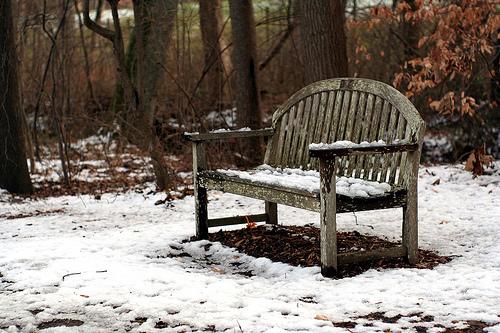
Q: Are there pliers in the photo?
A: No, there are no pliers.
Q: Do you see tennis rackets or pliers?
A: No, there are no pliers or tennis rackets.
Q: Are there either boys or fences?
A: No, there are no fences or boys.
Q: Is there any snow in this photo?
A: Yes, there is snow.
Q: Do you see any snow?
A: Yes, there is snow.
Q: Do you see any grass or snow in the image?
A: Yes, there is snow.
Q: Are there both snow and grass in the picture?
A: No, there is snow but no grass.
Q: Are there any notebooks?
A: No, there are no notebooks.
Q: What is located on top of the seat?
A: The snow is on top of the seat.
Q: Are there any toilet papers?
A: No, there are no toilet papers.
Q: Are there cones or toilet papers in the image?
A: No, there are no toilet papers or cones.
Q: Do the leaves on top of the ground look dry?
A: Yes, the leaves are dry.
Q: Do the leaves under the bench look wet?
A: No, the leaves are dry.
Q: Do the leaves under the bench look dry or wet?
A: The leaves are dry.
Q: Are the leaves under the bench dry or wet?
A: The leaves are dry.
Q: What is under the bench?
A: The leaves are under the bench.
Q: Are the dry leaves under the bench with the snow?
A: Yes, the leaves are under the bench.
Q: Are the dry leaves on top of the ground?
A: Yes, the leaves are on top of the ground.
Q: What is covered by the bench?
A: The leaves are covered by the bench.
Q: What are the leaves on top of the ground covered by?
A: The leaves are covered by the bench.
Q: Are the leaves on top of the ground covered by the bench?
A: Yes, the leaves are covered by the bench.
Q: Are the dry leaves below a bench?
A: Yes, the leaves are below a bench.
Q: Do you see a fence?
A: No, there are no fences.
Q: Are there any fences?
A: No, there are no fences.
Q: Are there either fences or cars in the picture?
A: No, there are no fences or cars.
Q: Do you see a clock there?
A: No, there are no clocks.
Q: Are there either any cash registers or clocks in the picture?
A: No, there are no clocks or cash registers.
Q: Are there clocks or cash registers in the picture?
A: No, there are no clocks or cash registers.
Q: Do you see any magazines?
A: No, there are no magazines.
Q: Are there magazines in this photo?
A: No, there are no magazines.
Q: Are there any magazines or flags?
A: No, there are no magazines or flags.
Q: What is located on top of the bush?
A: The branch is on top of the bush.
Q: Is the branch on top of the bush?
A: Yes, the branch is on top of the bush.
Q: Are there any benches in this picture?
A: Yes, there is a bench.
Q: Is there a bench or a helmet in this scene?
A: Yes, there is a bench.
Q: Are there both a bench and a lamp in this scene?
A: No, there is a bench but no lamps.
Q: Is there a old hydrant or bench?
A: Yes, there is an old bench.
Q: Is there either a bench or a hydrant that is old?
A: Yes, the bench is old.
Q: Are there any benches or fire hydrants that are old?
A: Yes, the bench is old.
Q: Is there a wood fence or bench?
A: Yes, there is a wood bench.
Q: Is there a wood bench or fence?
A: Yes, there is a wood bench.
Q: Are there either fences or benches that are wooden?
A: Yes, the bench is wooden.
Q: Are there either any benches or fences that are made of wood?
A: Yes, the bench is made of wood.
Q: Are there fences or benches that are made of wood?
A: Yes, the bench is made of wood.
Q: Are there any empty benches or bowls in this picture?
A: Yes, there is an empty bench.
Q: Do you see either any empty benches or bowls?
A: Yes, there is an empty bench.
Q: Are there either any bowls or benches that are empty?
A: Yes, the bench is empty.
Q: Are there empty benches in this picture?
A: Yes, there is an empty bench.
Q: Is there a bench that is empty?
A: Yes, there is a bench that is empty.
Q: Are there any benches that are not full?
A: Yes, there is a empty bench.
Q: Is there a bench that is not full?
A: Yes, there is a empty bench.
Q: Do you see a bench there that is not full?
A: Yes, there is a empty bench.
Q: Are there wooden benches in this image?
A: Yes, there is a wood bench.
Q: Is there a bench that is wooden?
A: Yes, there is a bench that is wooden.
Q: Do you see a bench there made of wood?
A: Yes, there is a bench that is made of wood.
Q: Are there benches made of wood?
A: Yes, there is a bench that is made of wood.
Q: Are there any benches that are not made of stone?
A: Yes, there is a bench that is made of wood.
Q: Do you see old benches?
A: Yes, there is an old bench.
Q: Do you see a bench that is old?
A: Yes, there is an old bench.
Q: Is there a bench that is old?
A: Yes, there is a bench that is old.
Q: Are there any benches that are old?
A: Yes, there is a bench that is old.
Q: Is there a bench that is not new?
A: Yes, there is a old bench.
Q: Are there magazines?
A: No, there are no magazines.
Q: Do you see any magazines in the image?
A: No, there are no magazines.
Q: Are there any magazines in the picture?
A: No, there are no magazines.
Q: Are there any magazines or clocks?
A: No, there are no magazines or clocks.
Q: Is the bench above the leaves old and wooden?
A: Yes, the bench is old and wooden.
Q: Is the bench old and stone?
A: No, the bench is old but wooden.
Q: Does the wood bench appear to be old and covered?
A: Yes, the bench is old and covered.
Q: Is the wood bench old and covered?
A: Yes, the bench is old and covered.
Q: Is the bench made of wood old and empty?
A: Yes, the bench is old and empty.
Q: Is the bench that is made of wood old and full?
A: No, the bench is old but empty.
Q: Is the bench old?
A: Yes, the bench is old.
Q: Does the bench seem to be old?
A: Yes, the bench is old.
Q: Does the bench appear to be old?
A: Yes, the bench is old.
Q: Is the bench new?
A: No, the bench is old.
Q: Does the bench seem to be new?
A: No, the bench is old.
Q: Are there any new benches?
A: No, there is a bench but it is old.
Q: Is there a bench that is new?
A: No, there is a bench but it is old.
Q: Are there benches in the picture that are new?
A: No, there is a bench but it is old.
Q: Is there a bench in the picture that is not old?
A: No, there is a bench but it is old.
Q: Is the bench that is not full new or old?
A: The bench is old.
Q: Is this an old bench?
A: Yes, this is an old bench.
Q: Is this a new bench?
A: No, this is an old bench.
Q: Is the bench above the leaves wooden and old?
A: Yes, the bench is wooden and old.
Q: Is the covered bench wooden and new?
A: No, the bench is wooden but old.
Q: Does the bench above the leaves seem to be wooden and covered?
A: Yes, the bench is wooden and covered.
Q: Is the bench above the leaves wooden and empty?
A: Yes, the bench is wooden and empty.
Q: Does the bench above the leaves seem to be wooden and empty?
A: Yes, the bench is wooden and empty.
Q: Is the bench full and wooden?
A: No, the bench is wooden but empty.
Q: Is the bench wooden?
A: Yes, the bench is wooden.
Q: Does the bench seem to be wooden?
A: Yes, the bench is wooden.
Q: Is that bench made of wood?
A: Yes, the bench is made of wood.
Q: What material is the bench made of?
A: The bench is made of wood.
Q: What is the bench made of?
A: The bench is made of wood.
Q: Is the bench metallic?
A: No, the bench is wooden.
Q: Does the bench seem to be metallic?
A: No, the bench is wooden.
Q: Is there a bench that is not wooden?
A: No, there is a bench but it is wooden.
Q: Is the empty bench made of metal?
A: No, the bench is made of wood.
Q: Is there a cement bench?
A: No, there is a bench but it is made of wood.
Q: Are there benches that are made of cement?
A: No, there is a bench but it is made of wood.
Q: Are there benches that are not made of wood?
A: No, there is a bench but it is made of wood.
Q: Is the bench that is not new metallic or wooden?
A: The bench is wooden.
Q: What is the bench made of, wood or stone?
A: The bench is made of wood.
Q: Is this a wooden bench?
A: Yes, this is a wooden bench.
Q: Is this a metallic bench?
A: No, this is a wooden bench.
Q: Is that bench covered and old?
A: Yes, the bench is covered and old.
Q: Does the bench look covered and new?
A: No, the bench is covered but old.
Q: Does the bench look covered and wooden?
A: Yes, the bench is covered and wooden.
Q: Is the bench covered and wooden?
A: Yes, the bench is covered and wooden.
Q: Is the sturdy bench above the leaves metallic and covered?
A: No, the bench is covered but wooden.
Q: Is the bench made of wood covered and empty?
A: Yes, the bench is covered and empty.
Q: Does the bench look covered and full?
A: No, the bench is covered but empty.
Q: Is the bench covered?
A: Yes, the bench is covered.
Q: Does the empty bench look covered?
A: Yes, the bench is covered.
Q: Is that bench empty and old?
A: Yes, the bench is empty and old.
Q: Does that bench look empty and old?
A: Yes, the bench is empty and old.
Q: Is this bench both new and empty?
A: No, the bench is empty but old.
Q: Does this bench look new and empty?
A: No, the bench is empty but old.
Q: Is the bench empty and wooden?
A: Yes, the bench is empty and wooden.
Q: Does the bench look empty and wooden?
A: Yes, the bench is empty and wooden.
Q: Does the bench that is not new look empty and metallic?
A: No, the bench is empty but wooden.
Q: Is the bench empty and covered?
A: Yes, the bench is empty and covered.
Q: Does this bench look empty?
A: Yes, the bench is empty.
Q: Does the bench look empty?
A: Yes, the bench is empty.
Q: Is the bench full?
A: No, the bench is empty.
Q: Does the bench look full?
A: No, the bench is empty.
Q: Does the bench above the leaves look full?
A: No, the bench is empty.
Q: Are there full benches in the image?
A: No, there is a bench but it is empty.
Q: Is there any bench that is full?
A: No, there is a bench but it is empty.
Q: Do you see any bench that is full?
A: No, there is a bench but it is empty.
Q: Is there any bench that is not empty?
A: No, there is a bench but it is empty.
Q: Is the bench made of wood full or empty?
A: The bench is empty.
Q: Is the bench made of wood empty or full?
A: The bench is empty.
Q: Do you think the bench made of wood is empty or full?
A: The bench is empty.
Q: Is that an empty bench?
A: Yes, that is an empty bench.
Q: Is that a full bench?
A: No, that is an empty bench.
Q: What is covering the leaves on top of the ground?
A: The bench is covering the leaves.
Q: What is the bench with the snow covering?
A: The bench is covering the leaves.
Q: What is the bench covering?
A: The bench is covering the leaves.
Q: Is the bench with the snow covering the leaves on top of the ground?
A: Yes, the bench is covering the leaves.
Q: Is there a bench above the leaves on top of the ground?
A: Yes, there is a bench above the leaves.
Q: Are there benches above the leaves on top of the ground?
A: Yes, there is a bench above the leaves.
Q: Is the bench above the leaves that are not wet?
A: Yes, the bench is above the leaves.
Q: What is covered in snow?
A: The bench is covered in snow.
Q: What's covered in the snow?
A: The bench is covered in snow.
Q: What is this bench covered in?
A: The bench is covered in snow.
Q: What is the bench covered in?
A: The bench is covered in snow.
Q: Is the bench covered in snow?
A: Yes, the bench is covered in snow.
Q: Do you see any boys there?
A: No, there are no boys.